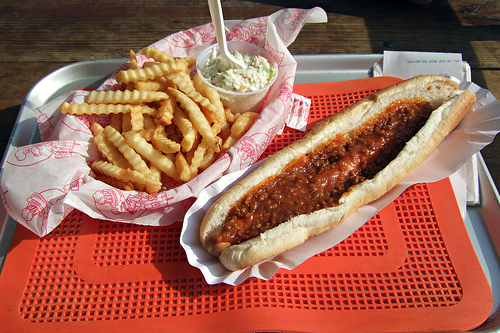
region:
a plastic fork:
[204, 0, 241, 68]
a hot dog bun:
[198, 73, 475, 270]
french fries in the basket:
[41, 54, 254, 202]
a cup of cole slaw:
[197, 42, 278, 99]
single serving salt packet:
[288, 94, 310, 131]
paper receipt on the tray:
[383, 49, 463, 217]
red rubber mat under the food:
[0, 78, 490, 328]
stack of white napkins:
[370, 59, 481, 206]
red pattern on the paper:
[21, 178, 87, 223]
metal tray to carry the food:
[3, 55, 498, 309]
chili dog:
[205, 95, 472, 279]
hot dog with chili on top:
[213, 94, 443, 259]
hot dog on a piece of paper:
[180, 74, 462, 282]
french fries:
[73, 90, 154, 137]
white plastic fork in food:
[197, 7, 261, 79]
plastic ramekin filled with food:
[200, 42, 271, 99]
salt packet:
[282, 92, 315, 130]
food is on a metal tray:
[41, 73, 498, 328]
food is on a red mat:
[45, 56, 478, 331]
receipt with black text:
[371, 47, 469, 79]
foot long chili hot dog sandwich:
[191, 66, 481, 276]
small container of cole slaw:
[192, 37, 279, 114]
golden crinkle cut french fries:
[58, 38, 260, 193]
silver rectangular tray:
[4, 47, 499, 327]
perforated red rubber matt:
[5, 73, 499, 329]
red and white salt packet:
[280, 85, 310, 135]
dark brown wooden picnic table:
[0, 0, 497, 145]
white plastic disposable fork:
[203, 0, 245, 74]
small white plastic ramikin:
[191, 34, 280, 109]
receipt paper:
[377, 43, 483, 206]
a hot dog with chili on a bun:
[203, 155, 458, 295]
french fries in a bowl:
[87, 45, 202, 190]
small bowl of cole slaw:
[205, 12, 251, 97]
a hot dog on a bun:
[206, 72, 473, 279]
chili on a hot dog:
[257, 97, 421, 249]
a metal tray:
[20, 35, 460, 164]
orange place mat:
[364, 137, 451, 331]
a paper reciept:
[368, 50, 470, 92]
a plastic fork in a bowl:
[184, 17, 267, 107]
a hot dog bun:
[190, 104, 470, 309]